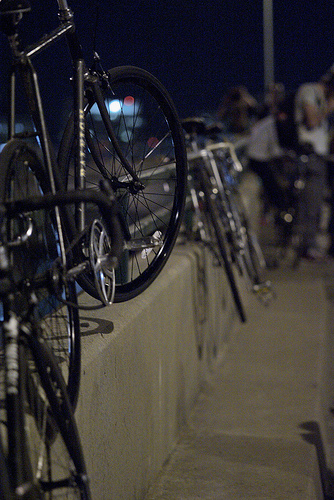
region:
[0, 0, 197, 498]
black bicycle parked on concrete wall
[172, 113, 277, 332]
bicycle parked on concrete wall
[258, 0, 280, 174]
metal light pole attached to concrete wall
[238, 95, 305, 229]
person sitting on concrete wall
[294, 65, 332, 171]
person wearing white shirt sitting on concrete wall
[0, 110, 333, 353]
metal railing on concrete wall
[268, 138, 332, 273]
bicycle parked along concrete wall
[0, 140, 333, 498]
thick concrete wall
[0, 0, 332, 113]
dark blue night sky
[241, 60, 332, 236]
group of people sitting on wall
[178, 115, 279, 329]
bikes are leaning against the bridge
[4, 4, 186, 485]
bikes are stacked up on the cement wall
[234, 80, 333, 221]
people and bikes are hanging out on the bridge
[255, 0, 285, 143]
a pole is on the bridge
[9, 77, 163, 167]
lights are in the background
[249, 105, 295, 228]
a peson is sitting on the bridge wall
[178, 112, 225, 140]
the bikes have black seats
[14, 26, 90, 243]
the bike frame is black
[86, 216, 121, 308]
the bike sprocket is silver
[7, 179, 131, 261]
the handles are black on the bike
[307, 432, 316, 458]
the shadow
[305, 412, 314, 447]
the shadow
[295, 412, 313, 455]
the shadow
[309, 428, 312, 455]
the shadow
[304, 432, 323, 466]
the shadow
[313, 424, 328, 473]
the shadow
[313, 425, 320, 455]
the shadow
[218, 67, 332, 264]
People hanging out on the side of a bridge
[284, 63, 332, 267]
Man in a white t-shirt standing on side of a bridge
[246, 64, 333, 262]
Bicyclists resting on the bridge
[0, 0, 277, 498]
Bicycles on the ramp and side of a bridge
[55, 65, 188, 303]
Front tire to a black bike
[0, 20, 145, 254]
Black frame to the bike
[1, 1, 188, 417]
A bicycle on the top of the bridge's ramp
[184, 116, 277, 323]
Two bikes with front tires on the ramp of the bridge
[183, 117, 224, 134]
Two black seats to the bikes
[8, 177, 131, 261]
Black handlebar to the bike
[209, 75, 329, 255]
Group of people standing by the wall.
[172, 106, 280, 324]
Bike fixed to the railing on the wall.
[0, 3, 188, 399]
Black bike parked on top of a wall.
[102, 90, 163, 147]
Blurry lights in the distance.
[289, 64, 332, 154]
Man wearing a white shirt.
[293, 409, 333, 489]
Shadow of a an object on the ground.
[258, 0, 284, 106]
Tall light post along the sidewalk.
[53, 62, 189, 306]
Black front tire of the bicycle.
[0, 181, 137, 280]
Front handlebars of the bicycle painted black.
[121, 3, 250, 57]
Clear nighttime sky.